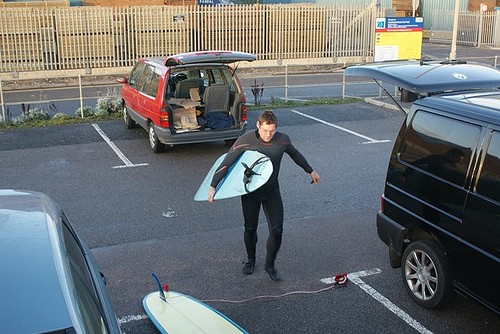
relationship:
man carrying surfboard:
[206, 110, 321, 281] [192, 149, 274, 202]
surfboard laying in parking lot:
[136, 272, 253, 331] [0, 72, 499, 332]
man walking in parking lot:
[206, 110, 321, 281] [0, 72, 499, 332]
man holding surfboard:
[206, 110, 321, 281] [186, 146, 275, 201]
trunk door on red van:
[162, 47, 256, 63] [117, 50, 256, 150]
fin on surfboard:
[148, 269, 170, 302] [141, 287, 250, 332]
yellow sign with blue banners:
[374, 25, 424, 63] [373, 13, 428, 26]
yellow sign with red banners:
[374, 25, 424, 63] [368, 25, 423, 30]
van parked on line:
[118, 51, 255, 148] [85, 117, 150, 172]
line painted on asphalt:
[85, 117, 150, 172] [113, 128, 377, 303]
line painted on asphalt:
[344, 277, 409, 332] [309, 250, 398, 330]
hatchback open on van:
[162, 47, 254, 137] [118, 51, 255, 148]